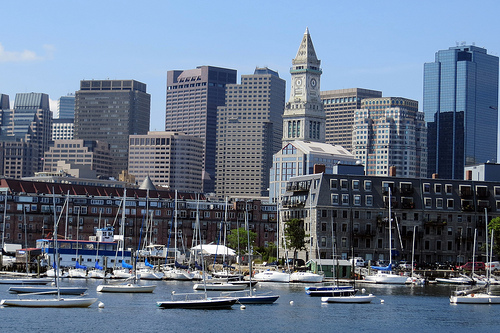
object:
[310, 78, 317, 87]
clock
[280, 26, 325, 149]
clocktower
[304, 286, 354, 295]
boat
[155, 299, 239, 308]
boat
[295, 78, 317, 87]
clock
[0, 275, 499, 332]
ocean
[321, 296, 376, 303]
boat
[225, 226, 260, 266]
palm tree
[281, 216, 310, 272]
palm tree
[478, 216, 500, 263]
palm tree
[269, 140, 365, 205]
building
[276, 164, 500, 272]
building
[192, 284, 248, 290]
boat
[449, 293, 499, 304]
boat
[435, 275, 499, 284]
boat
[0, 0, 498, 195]
sky building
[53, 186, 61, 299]
pole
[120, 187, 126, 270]
pole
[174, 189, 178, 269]
pole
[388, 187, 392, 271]
pole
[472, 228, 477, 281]
pole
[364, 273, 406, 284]
boat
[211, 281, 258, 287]
boat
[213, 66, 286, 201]
building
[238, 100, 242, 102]
window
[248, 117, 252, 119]
window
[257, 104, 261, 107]
window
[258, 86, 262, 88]
window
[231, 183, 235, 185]
window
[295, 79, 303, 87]
clock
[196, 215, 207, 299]
pole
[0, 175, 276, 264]
building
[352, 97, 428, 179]
building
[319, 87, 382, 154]
building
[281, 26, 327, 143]
building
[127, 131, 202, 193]
building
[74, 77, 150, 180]
building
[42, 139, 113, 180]
building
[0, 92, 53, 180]
building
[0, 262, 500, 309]
boats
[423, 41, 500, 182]
building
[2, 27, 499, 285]
city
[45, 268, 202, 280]
boat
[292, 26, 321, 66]
steeple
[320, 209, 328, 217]
window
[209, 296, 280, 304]
boat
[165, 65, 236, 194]
building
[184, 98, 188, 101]
windows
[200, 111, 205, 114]
windows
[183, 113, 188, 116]
windows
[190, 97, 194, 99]
windows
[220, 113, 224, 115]
windows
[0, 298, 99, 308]
boat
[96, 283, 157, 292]
boat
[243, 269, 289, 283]
boat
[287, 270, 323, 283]
boat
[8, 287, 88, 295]
boat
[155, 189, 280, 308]
object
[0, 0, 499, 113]
sky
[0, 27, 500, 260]
buildings